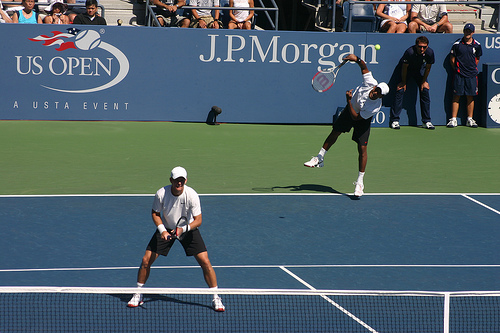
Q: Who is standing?
A: The man is standing.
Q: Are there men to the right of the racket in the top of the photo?
A: Yes, there is a man to the right of the tennis racket.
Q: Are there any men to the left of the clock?
A: Yes, there is a man to the left of the clock.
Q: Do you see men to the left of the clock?
A: Yes, there is a man to the left of the clock.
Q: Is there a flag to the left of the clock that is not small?
A: No, there is a man to the left of the clock.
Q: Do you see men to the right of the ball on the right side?
A: Yes, there is a man to the right of the ball.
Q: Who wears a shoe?
A: The man wears a shoe.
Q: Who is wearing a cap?
A: The man is wearing a cap.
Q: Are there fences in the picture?
A: No, there are no fences.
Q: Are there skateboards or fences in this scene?
A: No, there are no fences or skateboards.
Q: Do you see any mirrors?
A: No, there are no mirrors.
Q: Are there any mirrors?
A: No, there are no mirrors.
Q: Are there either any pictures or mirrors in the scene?
A: No, there are no mirrors or pictures.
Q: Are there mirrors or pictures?
A: No, there are no mirrors or pictures.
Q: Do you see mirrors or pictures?
A: No, there are no mirrors or pictures.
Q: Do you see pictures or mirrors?
A: No, there are no mirrors or pictures.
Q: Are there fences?
A: No, there are no fences.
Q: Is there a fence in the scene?
A: No, there are no fences.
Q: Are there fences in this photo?
A: No, there are no fences.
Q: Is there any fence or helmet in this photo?
A: No, there are no fences or helmets.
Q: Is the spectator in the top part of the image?
A: Yes, the spectator is in the top of the image.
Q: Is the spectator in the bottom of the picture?
A: No, the spectator is in the top of the image.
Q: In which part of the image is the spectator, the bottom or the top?
A: The spectator is in the top of the image.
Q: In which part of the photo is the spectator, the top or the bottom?
A: The spectator is in the top of the image.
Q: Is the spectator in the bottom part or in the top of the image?
A: The spectator is in the top of the image.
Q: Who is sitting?
A: The spectator is sitting.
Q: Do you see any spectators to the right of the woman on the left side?
A: Yes, there is a spectator to the right of the woman.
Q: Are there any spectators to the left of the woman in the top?
A: No, the spectator is to the right of the woman.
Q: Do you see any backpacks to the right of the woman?
A: No, there is a spectator to the right of the woman.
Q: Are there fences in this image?
A: No, there are no fences.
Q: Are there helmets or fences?
A: No, there are no fences or helmets.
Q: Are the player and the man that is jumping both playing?
A: Yes, both the player and the man are playing.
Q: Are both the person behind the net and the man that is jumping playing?
A: Yes, both the player and the man are playing.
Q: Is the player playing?
A: Yes, the player is playing.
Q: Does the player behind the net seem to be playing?
A: Yes, the player is playing.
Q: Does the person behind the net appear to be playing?
A: Yes, the player is playing.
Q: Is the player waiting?
A: No, the player is playing.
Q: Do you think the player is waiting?
A: No, the player is playing.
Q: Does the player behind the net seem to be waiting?
A: No, the player is playing.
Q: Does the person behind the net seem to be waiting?
A: No, the player is playing.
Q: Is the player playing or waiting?
A: The player is playing.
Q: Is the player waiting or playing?
A: The player is playing.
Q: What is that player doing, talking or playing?
A: The player is playing.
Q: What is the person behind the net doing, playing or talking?
A: The player is playing.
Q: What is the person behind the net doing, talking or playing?
A: The player is playing.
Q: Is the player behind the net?
A: Yes, the player is behind the net.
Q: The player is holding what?
A: The player is holding the tennis racket.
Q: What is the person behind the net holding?
A: The player is holding the tennis racket.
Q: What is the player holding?
A: The player is holding the tennis racket.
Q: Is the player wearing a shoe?
A: Yes, the player is wearing a shoe.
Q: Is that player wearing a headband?
A: No, the player is wearing a shoe.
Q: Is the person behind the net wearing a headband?
A: No, the player is wearing a shoe.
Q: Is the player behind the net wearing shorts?
A: Yes, the player is wearing shorts.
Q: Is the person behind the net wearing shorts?
A: Yes, the player is wearing shorts.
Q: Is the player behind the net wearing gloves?
A: No, the player is wearing shorts.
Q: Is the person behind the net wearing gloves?
A: No, the player is wearing shorts.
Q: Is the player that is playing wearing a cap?
A: Yes, the player is wearing a cap.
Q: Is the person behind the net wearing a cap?
A: Yes, the player is wearing a cap.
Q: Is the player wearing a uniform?
A: No, the player is wearing a cap.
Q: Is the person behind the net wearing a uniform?
A: No, the player is wearing a cap.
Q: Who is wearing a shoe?
A: The player is wearing a shoe.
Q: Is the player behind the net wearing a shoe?
A: Yes, the player is wearing a shoe.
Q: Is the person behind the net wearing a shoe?
A: Yes, the player is wearing a shoe.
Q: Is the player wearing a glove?
A: No, the player is wearing a shoe.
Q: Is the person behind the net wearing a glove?
A: No, the player is wearing a shoe.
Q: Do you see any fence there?
A: No, there are no fences.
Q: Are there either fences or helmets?
A: No, there are no fences or helmets.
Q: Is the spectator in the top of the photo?
A: Yes, the spectator is in the top of the image.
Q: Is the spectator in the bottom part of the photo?
A: No, the spectator is in the top of the image.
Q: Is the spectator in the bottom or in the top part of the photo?
A: The spectator is in the top of the image.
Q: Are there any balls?
A: Yes, there is a ball.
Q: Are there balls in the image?
A: Yes, there is a ball.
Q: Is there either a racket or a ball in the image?
A: Yes, there is a ball.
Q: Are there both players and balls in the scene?
A: Yes, there are both a ball and a player.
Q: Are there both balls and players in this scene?
A: Yes, there are both a ball and a player.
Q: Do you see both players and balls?
A: Yes, there are both a ball and a player.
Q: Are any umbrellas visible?
A: No, there are no umbrellas.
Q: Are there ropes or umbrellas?
A: No, there are no umbrellas or ropes.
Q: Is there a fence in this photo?
A: No, there are no fences.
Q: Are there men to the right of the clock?
A: No, the man is to the left of the clock.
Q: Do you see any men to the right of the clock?
A: No, the man is to the left of the clock.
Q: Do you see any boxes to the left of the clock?
A: No, there is a man to the left of the clock.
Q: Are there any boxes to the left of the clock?
A: No, there is a man to the left of the clock.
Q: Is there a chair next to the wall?
A: No, there is a man next to the wall.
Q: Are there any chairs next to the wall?
A: No, there is a man next to the wall.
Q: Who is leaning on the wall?
A: The man is leaning on the wall.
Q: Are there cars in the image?
A: No, there are no cars.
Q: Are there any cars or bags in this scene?
A: No, there are no cars or bags.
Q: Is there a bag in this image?
A: No, there are no bags.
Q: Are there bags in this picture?
A: No, there are no bags.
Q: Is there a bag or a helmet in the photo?
A: No, there are no bags or helmets.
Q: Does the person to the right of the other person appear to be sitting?
A: Yes, the person is sitting.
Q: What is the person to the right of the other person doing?
A: The person is sitting.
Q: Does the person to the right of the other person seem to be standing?
A: No, the person is sitting.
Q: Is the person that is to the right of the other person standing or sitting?
A: The person is sitting.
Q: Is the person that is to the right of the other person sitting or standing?
A: The person is sitting.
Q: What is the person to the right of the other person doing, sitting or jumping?
A: The person is sitting.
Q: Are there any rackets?
A: Yes, there is a racket.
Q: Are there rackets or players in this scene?
A: Yes, there is a racket.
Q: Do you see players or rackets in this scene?
A: Yes, there is a racket.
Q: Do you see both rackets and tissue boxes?
A: No, there is a racket but no tissue boxes.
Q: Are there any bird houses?
A: No, there are no bird houses.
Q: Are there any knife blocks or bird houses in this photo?
A: No, there are no bird houses or knife blocks.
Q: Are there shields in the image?
A: No, there are no shields.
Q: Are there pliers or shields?
A: No, there are no shields or pliers.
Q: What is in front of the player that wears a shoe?
A: The net is in front of the player.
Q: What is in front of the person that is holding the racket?
A: The net is in front of the player.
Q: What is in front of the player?
A: The net is in front of the player.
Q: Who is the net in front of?
A: The net is in front of the player.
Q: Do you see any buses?
A: No, there are no buses.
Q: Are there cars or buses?
A: No, there are no buses or cars.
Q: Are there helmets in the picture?
A: No, there are no helmets.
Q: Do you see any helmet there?
A: No, there are no helmets.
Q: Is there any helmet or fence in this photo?
A: No, there are no helmets or fences.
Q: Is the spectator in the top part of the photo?
A: Yes, the spectator is in the top of the image.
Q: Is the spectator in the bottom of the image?
A: No, the spectator is in the top of the image.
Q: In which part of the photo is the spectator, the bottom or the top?
A: The spectator is in the top of the image.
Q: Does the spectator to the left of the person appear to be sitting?
A: Yes, the spectator is sitting.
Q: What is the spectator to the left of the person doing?
A: The spectator is sitting.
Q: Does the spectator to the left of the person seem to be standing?
A: No, the spectator is sitting.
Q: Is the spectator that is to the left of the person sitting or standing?
A: The spectator is sitting.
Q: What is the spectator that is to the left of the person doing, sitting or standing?
A: The spectator is sitting.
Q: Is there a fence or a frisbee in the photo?
A: No, there are no fences or frisbees.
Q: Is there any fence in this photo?
A: No, there are no fences.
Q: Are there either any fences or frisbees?
A: No, there are no fences or frisbees.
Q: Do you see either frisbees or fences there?
A: No, there are no fences or frisbees.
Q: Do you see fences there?
A: No, there are no fences.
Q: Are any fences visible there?
A: No, there are no fences.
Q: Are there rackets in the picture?
A: Yes, there is a racket.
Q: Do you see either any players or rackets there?
A: Yes, there is a racket.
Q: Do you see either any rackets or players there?
A: Yes, there is a racket.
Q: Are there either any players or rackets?
A: Yes, there is a racket.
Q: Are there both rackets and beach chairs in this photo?
A: No, there is a racket but no beach chairs.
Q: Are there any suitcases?
A: No, there are no suitcases.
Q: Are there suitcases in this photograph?
A: No, there are no suitcases.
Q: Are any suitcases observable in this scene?
A: No, there are no suitcases.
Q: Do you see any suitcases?
A: No, there are no suitcases.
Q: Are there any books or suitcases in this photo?
A: No, there are no suitcases or books.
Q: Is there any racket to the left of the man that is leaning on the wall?
A: Yes, there is a racket to the left of the man.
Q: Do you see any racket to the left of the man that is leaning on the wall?
A: Yes, there is a racket to the left of the man.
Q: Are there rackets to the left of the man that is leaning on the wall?
A: Yes, there is a racket to the left of the man.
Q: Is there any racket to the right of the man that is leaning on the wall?
A: No, the racket is to the left of the man.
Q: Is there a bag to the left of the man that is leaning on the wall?
A: No, there is a racket to the left of the man.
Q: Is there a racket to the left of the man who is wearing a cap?
A: Yes, there is a racket to the left of the man.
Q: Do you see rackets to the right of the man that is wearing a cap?
A: No, the racket is to the left of the man.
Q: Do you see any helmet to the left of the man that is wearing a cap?
A: No, there is a racket to the left of the man.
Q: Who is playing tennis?
A: The man is playing tennis.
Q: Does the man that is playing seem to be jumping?
A: Yes, the man is jumping.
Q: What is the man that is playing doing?
A: The man is jumping.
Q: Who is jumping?
A: The man is jumping.